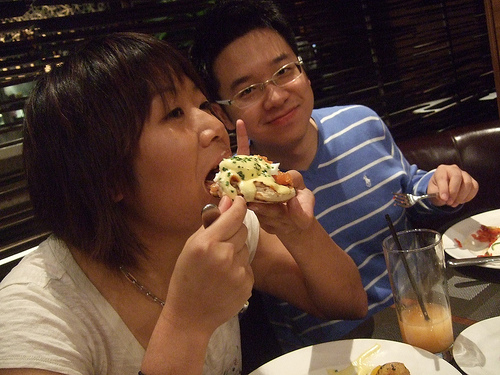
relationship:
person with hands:
[2, 47, 372, 343] [177, 129, 318, 320]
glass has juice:
[381, 221, 457, 350] [398, 298, 451, 351]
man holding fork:
[189, 0, 467, 314] [384, 186, 440, 206]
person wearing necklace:
[2, 47, 372, 343] [105, 247, 166, 307]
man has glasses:
[189, 0, 467, 314] [214, 61, 307, 111]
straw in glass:
[385, 212, 431, 320] [381, 221, 457, 350]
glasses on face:
[214, 61, 307, 111] [214, 50, 307, 139]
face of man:
[214, 50, 307, 139] [189, 0, 467, 314]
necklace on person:
[105, 247, 166, 307] [2, 47, 372, 343]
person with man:
[2, 47, 372, 343] [189, 0, 467, 314]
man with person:
[189, 0, 467, 314] [2, 47, 372, 343]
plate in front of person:
[242, 335, 466, 374] [2, 47, 372, 343]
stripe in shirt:
[320, 133, 385, 176] [212, 101, 444, 341]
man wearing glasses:
[189, 0, 467, 314] [214, 61, 307, 111]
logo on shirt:
[357, 170, 377, 187] [212, 101, 444, 341]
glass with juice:
[381, 221, 457, 350] [398, 298, 451, 351]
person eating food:
[2, 47, 372, 343] [210, 152, 300, 208]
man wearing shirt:
[189, 0, 467, 314] [212, 101, 444, 341]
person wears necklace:
[2, 47, 372, 343] [105, 247, 166, 307]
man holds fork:
[189, 0, 467, 314] [384, 186, 440, 206]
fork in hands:
[384, 186, 440, 206] [431, 159, 480, 211]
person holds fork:
[2, 47, 372, 343] [384, 186, 440, 206]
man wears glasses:
[189, 0, 467, 314] [214, 61, 307, 111]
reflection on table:
[455, 286, 499, 311] [315, 261, 499, 342]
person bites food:
[2, 47, 372, 343] [210, 152, 300, 208]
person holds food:
[2, 47, 372, 343] [210, 152, 300, 208]